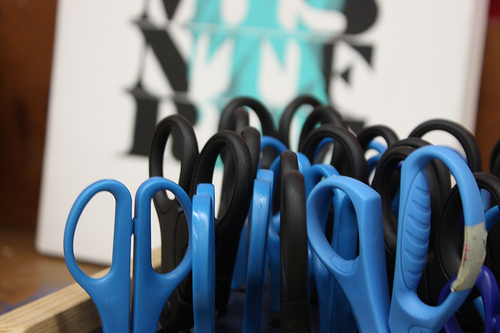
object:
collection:
[60, 174, 197, 333]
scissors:
[273, 149, 313, 332]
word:
[124, 20, 382, 109]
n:
[129, 0, 192, 92]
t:
[202, 29, 292, 104]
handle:
[452, 223, 490, 292]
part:
[190, 209, 214, 265]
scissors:
[305, 146, 487, 332]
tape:
[443, 226, 491, 297]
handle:
[244, 162, 276, 294]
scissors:
[241, 169, 280, 333]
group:
[63, 95, 497, 331]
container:
[3, 248, 164, 332]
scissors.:
[147, 114, 259, 333]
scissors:
[61, 177, 190, 333]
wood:
[3, 281, 86, 333]